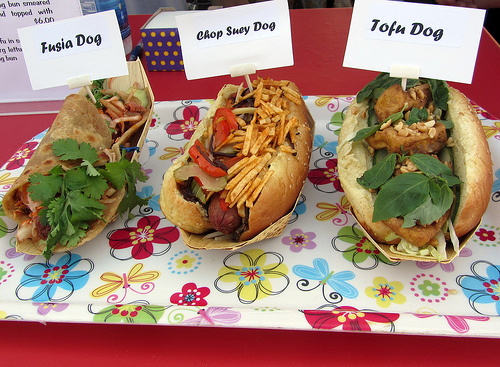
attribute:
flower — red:
[108, 213, 179, 261]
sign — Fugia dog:
[12, 12, 132, 83]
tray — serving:
[15, 112, 498, 345]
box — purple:
[138, 3, 226, 73]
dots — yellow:
[140, 30, 187, 73]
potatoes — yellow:
[219, 75, 304, 218]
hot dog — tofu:
[337, 72, 492, 261]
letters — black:
[371, 11, 443, 41]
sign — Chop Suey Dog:
[162, 3, 312, 94]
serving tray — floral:
[0, 94, 498, 337]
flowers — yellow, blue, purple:
[24, 239, 441, 334]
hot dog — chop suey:
[171, 59, 294, 253]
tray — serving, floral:
[3, 70, 495, 329]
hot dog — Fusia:
[7, 50, 161, 237]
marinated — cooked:
[369, 117, 450, 155]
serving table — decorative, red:
[2, 12, 499, 362]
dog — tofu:
[383, 93, 437, 222]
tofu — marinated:
[380, 93, 441, 153]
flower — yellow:
[233, 274, 265, 289]